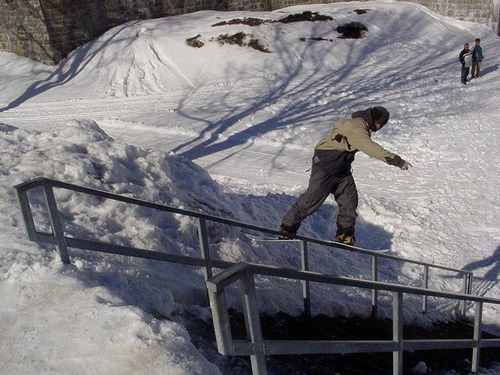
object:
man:
[279, 106, 413, 246]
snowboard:
[244, 233, 390, 253]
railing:
[13, 177, 499, 375]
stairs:
[272, 310, 351, 373]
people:
[458, 42, 472, 84]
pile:
[0, 117, 342, 270]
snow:
[2, 1, 496, 374]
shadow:
[438, 245, 499, 281]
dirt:
[187, 10, 369, 52]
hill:
[52, 0, 487, 87]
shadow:
[169, 8, 499, 167]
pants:
[281, 167, 359, 233]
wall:
[1, 0, 499, 65]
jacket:
[459, 48, 472, 67]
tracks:
[144, 29, 195, 89]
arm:
[356, 133, 403, 165]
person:
[471, 37, 485, 79]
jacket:
[471, 45, 485, 63]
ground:
[1, 1, 499, 374]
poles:
[41, 183, 71, 265]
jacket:
[312, 115, 405, 179]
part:
[205, 261, 499, 374]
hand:
[400, 161, 412, 171]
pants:
[461, 66, 470, 83]